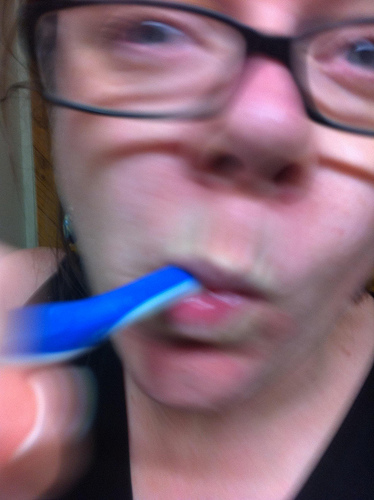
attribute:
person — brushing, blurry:
[1, 1, 373, 500]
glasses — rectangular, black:
[18, 0, 373, 138]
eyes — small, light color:
[113, 17, 374, 73]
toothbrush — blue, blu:
[1, 265, 203, 368]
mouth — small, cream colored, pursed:
[149, 255, 276, 327]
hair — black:
[0, 0, 90, 302]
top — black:
[4, 251, 373, 499]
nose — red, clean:
[192, 41, 315, 197]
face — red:
[52, 0, 373, 407]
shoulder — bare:
[1, 242, 68, 307]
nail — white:
[9, 375, 47, 455]